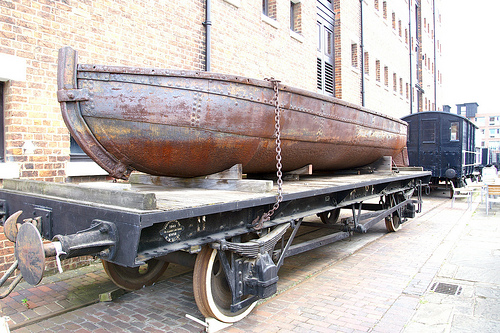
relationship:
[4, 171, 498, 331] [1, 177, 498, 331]
red brick on pavement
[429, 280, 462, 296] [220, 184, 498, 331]
vent in sidewalk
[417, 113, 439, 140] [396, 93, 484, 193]
windows in train car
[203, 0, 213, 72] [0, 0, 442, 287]
pipe on wall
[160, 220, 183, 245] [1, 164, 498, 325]
sticker in platform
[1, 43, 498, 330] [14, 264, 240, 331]
train on track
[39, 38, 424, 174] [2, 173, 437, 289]
boat tied to cart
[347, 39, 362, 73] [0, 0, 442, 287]
window attached to wall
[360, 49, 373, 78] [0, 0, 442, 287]
window attached to wall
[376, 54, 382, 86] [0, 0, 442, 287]
window attached to wall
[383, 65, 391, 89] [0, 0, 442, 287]
window attached to wall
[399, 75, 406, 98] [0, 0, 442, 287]
window attached to wall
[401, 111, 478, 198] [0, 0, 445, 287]
train car near building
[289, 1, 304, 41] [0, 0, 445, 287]
window on building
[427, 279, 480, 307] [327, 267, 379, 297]
drain on ground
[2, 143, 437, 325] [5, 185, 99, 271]
trailer has hitch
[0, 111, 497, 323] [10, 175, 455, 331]
train on track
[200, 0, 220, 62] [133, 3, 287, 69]
pipe on wall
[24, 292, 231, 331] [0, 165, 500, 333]
shadow on floor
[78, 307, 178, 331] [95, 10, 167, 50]
brick on wall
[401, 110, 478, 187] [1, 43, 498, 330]
black engine of a train